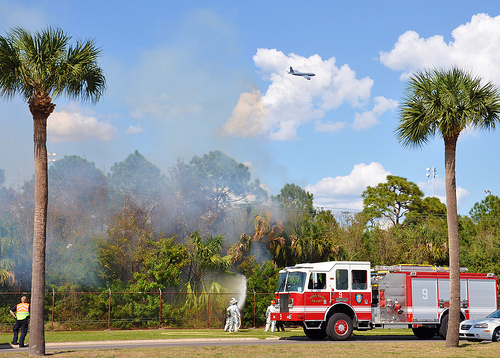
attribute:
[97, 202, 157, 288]
tree — burnt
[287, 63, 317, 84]
plane — flying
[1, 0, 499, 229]
sky — blue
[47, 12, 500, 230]
cloud — white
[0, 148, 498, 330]
forest — smoking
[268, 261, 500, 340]
firetruck — parked, red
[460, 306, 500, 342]
car — white, parked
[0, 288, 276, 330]
fence — red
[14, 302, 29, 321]
vest — yellow, orange, green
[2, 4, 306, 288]
smoke — rising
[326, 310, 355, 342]
wheel — black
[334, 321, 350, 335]
rim — red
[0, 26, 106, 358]
tree — tall